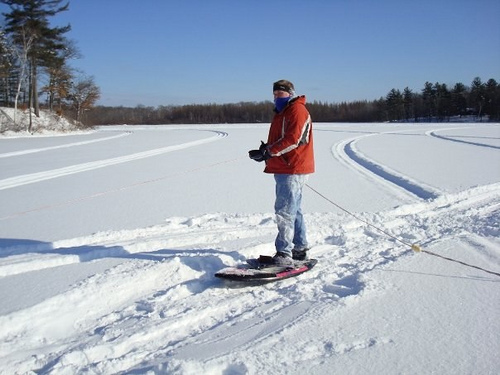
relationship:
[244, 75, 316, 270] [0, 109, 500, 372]
man in snow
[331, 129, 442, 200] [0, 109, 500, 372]
tracks in snow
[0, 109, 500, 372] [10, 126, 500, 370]
snow covering field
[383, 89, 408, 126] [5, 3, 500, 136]
tree in background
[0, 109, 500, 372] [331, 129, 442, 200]
snow has tracks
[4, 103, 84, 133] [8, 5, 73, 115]
hill next to tree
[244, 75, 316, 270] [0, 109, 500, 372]
man standing in snow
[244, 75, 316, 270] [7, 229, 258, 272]
man has shadow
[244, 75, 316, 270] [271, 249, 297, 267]
man has shoe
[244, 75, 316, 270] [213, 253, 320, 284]
man riding board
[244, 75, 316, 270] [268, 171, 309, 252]
man wearing pants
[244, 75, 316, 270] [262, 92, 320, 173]
man wearing coat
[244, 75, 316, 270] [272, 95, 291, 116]
man has mask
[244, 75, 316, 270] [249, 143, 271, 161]
man wearing gloves